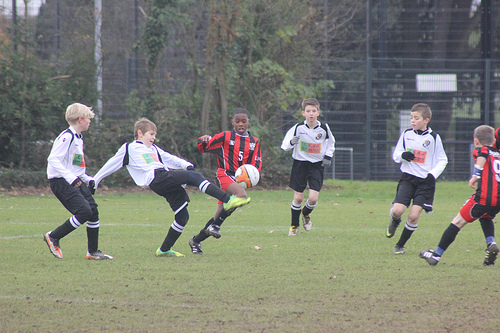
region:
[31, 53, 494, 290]
kids playing soccer together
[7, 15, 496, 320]
soccer field for kids to play on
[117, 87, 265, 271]
different uniforms indicating competition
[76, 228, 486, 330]
patch of the grass that is worn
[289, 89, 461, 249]
team mates dressed alike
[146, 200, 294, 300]
green and yellow athletic shoes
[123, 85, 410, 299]
tree and fence in the background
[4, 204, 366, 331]
lines on the field fading from use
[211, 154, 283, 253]
soccer ball being kicked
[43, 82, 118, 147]
only blonde child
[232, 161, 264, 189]
orange and white soccer ball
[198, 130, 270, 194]
red, black, and white soccer uniform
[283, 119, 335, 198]
white and black soccer uniform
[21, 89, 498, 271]
six boys playing soccer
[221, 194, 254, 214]
yellow and green soccer cleats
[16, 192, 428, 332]
green grass soccer field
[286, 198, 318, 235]
black and white knee length socks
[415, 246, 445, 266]
black and white soccer cleats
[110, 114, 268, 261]
boy kicking a soccer ball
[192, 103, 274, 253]
boy kicking soccer ball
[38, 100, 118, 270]
Boy in white and black soccer uniform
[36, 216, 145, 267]
White and orange shoes on a boy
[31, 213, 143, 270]
Black and white socks on a boy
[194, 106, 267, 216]
Red and black soccer uniform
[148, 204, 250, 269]
Green and yellow shoes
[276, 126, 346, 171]
Gray gloves on a boy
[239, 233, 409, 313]
Green and brown soccer field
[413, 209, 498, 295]
Black and blue soccer socks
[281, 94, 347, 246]
Boy running on a field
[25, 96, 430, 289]
Boys playing soccer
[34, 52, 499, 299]
young boys playing soccer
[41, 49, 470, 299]
children playing soccer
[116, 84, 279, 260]
boys' soccer game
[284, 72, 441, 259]
soccer team mates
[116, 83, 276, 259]
members of opposing team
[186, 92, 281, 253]
kicking soccer ball with knee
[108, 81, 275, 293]
attempting to steal soccer ball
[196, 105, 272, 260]
young black boy playing soccer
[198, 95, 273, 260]
red and black soccer uniform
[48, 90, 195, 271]
black and white soccer uniforms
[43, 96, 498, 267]
kids are playing soccer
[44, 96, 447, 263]
four kids wearing black and white uniforms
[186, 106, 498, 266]
three kids wearing red and black uniforms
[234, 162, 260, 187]
one player kicking white and orange soccer ball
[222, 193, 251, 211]
green shoe under soccer ball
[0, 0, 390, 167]
trees behind players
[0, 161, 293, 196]
short hedge behind players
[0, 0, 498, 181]
tall fence behind players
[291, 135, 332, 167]
one player wearing gray gloves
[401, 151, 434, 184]
one player wearing black gloves